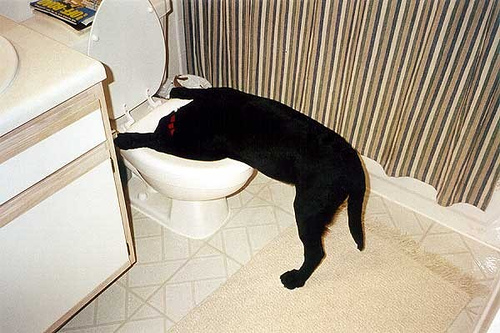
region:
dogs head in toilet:
[117, 86, 262, 205]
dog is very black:
[110, 84, 367, 289]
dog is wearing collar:
[165, 109, 177, 137]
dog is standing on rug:
[117, 86, 485, 331]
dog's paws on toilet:
[115, 82, 366, 289]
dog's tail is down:
[344, 184, 371, 251]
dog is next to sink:
[0, 15, 365, 332]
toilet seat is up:
[89, 1, 256, 237]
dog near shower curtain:
[114, 1, 499, 289]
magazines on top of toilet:
[20, 1, 253, 238]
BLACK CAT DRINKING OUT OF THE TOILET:
[85, 0, 392, 295]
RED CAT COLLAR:
[160, 105, 181, 135]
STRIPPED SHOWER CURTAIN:
[175, 0, 491, 210]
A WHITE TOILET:
[26, 0, 251, 242]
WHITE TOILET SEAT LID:
[80, 0, 185, 121]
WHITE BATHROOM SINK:
[0, 15, 140, 285]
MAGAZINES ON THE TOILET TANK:
[26, 0, 141, 35]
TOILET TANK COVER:
[15, 0, 175, 60]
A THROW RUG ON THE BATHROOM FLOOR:
[167, 196, 488, 326]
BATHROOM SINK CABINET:
[0, 146, 140, 323]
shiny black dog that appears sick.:
[112, 85, 363, 287]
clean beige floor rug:
[160, 205, 485, 330]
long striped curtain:
[180, 0, 495, 215]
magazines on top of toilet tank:
[30, 0, 100, 35]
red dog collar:
[165, 110, 170, 130]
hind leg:
[275, 180, 330, 295]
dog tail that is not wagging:
[345, 150, 365, 245]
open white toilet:
[85, 0, 251, 236]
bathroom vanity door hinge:
[105, 155, 110, 170]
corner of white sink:
[0, 35, 18, 90]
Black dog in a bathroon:
[106, 70, 386, 292]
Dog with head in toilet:
[142, 91, 230, 166]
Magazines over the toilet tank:
[30, 0, 170, 35]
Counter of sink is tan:
[0, 0, 140, 320]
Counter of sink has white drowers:
[0, 12, 150, 327]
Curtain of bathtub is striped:
[170, 0, 495, 225]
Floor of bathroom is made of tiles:
[101, 183, 471, 329]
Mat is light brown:
[158, 200, 485, 330]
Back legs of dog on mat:
[268, 181, 349, 297]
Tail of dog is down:
[340, 173, 377, 253]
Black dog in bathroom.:
[112, 82, 379, 292]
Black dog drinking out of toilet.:
[115, 85, 365, 289]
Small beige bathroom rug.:
[155, 209, 483, 330]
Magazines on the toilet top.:
[27, 1, 107, 37]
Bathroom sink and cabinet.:
[0, 16, 136, 331]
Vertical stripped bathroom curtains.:
[180, 0, 499, 213]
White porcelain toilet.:
[20, 0, 253, 239]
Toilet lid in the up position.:
[87, 0, 164, 122]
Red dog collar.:
[167, 115, 174, 138]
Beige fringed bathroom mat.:
[169, 199, 488, 330]